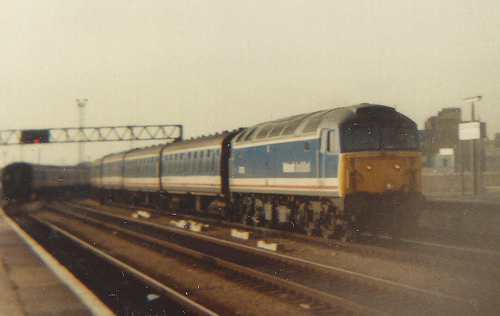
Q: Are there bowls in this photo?
A: No, there are no bowls.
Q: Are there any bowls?
A: No, there are no bowls.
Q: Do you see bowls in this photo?
A: No, there are no bowls.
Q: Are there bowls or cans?
A: No, there are no bowls or cans.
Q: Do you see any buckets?
A: No, there are no buckets.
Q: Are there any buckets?
A: No, there are no buckets.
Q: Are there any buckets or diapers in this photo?
A: No, there are no buckets or diapers.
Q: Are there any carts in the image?
A: No, there are no carts.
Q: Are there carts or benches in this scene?
A: No, there are no carts or benches.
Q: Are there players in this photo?
A: No, there are no players.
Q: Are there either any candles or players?
A: No, there are no players or candles.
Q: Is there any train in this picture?
A: Yes, there is a train.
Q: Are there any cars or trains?
A: Yes, there is a train.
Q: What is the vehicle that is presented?
A: The vehicle is a train.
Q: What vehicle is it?
A: The vehicle is a train.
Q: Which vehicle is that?
A: This is a train.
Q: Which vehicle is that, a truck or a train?
A: This is a train.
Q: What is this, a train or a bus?
A: This is a train.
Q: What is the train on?
A: The train is on the tracks.